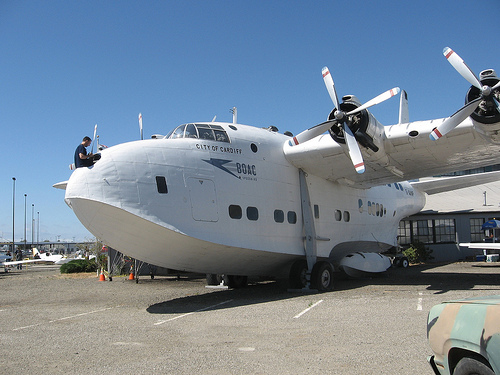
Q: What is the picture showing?
A: It is showing an airport.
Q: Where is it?
A: This is at the airport.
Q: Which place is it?
A: It is an airport.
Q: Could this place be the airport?
A: Yes, it is the airport.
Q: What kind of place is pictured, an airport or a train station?
A: It is an airport.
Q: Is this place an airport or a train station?
A: It is an airport.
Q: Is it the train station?
A: No, it is the airport.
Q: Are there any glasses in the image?
A: No, there are no glasses.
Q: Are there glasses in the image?
A: No, there are no glasses.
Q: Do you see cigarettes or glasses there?
A: No, there are no glasses or cigarettes.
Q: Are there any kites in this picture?
A: No, there are no kites.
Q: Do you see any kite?
A: No, there are no kites.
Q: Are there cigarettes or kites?
A: No, there are no kites or cigarettes.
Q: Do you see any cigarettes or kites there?
A: No, there are no kites or cigarettes.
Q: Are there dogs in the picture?
A: No, there are no dogs.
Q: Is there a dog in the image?
A: No, there are no dogs.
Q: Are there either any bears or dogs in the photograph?
A: No, there are no dogs or bears.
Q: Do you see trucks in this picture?
A: Yes, there is a truck.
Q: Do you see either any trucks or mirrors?
A: Yes, there is a truck.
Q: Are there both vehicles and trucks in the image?
A: Yes, there are both a truck and a vehicle.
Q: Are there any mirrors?
A: No, there are no mirrors.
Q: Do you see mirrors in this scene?
A: No, there are no mirrors.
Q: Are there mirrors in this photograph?
A: No, there are no mirrors.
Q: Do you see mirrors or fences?
A: No, there are no mirrors or fences.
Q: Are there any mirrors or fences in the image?
A: No, there are no mirrors or fences.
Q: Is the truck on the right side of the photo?
A: Yes, the truck is on the right of the image.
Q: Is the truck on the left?
A: No, the truck is on the right of the image.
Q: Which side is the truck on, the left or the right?
A: The truck is on the right of the image.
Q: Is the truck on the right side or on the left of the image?
A: The truck is on the right of the image.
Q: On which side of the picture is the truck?
A: The truck is on the right of the image.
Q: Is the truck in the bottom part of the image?
A: Yes, the truck is in the bottom of the image.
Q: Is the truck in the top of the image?
A: No, the truck is in the bottom of the image.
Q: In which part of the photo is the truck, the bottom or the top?
A: The truck is in the bottom of the image.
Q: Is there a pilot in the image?
A: No, there are no pilots.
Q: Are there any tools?
A: No, there are no tools.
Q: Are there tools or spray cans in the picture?
A: No, there are no tools or spray cans.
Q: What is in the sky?
A: The clouds are in the sky.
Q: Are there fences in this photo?
A: No, there are no fences.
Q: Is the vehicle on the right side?
A: Yes, the vehicle is on the right of the image.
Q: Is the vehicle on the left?
A: No, the vehicle is on the right of the image.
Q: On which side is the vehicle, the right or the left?
A: The vehicle is on the right of the image.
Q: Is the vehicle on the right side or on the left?
A: The vehicle is on the right of the image.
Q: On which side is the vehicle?
A: The vehicle is on the right of the image.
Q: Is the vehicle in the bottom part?
A: Yes, the vehicle is in the bottom of the image.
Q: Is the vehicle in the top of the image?
A: No, the vehicle is in the bottom of the image.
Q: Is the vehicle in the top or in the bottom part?
A: The vehicle is in the bottom of the image.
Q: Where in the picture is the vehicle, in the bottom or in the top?
A: The vehicle is in the bottom of the image.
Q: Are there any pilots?
A: No, there are no pilots.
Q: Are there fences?
A: No, there are no fences.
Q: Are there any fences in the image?
A: No, there are no fences.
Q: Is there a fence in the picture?
A: No, there are no fences.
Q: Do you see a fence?
A: No, there are no fences.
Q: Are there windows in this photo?
A: Yes, there is a window.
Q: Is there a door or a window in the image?
A: Yes, there is a window.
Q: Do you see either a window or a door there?
A: Yes, there is a window.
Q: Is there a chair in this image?
A: No, there are no chairs.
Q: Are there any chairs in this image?
A: No, there are no chairs.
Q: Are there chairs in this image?
A: No, there are no chairs.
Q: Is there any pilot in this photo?
A: No, there are no pilots.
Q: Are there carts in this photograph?
A: No, there are no carts.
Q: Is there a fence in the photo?
A: No, there are no fences.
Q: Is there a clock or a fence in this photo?
A: No, there are no fences or clocks.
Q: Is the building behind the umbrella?
A: Yes, the building is behind the umbrella.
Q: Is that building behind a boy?
A: No, the building is behind the umbrella.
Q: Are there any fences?
A: No, there are no fences.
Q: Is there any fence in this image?
A: No, there are no fences.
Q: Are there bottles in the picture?
A: No, there are no bottles.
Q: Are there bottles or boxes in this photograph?
A: No, there are no bottles or boxes.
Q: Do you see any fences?
A: No, there are no fences.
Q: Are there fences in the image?
A: No, there are no fences.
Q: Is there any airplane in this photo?
A: Yes, there is an airplane.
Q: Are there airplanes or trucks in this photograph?
A: Yes, there is an airplane.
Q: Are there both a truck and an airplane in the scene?
A: Yes, there are both an airplane and a truck.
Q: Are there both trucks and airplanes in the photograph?
A: Yes, there are both an airplane and a truck.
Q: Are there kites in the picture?
A: No, there are no kites.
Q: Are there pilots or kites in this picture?
A: No, there are no kites or pilots.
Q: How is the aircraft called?
A: The aircraft is an airplane.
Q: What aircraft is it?
A: The aircraft is an airplane.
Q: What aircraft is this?
A: This is an airplane.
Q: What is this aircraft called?
A: This is an airplane.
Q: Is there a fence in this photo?
A: No, there are no fences.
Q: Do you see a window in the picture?
A: Yes, there are windows.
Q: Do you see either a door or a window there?
A: Yes, there are windows.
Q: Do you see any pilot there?
A: No, there are no pilots.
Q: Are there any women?
A: No, there are no women.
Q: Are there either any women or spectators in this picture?
A: No, there are no women or spectators.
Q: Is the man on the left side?
A: Yes, the man is on the left of the image.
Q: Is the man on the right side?
A: No, the man is on the left of the image.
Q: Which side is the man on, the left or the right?
A: The man is on the left of the image.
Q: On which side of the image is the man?
A: The man is on the left of the image.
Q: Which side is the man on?
A: The man is on the left of the image.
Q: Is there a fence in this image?
A: No, there are no fences.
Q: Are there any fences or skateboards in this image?
A: No, there are no fences or skateboards.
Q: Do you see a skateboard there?
A: No, there are no skateboards.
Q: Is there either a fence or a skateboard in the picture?
A: No, there are no skateboards or fences.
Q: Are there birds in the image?
A: No, there are no birds.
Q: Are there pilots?
A: No, there are no pilots.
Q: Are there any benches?
A: No, there are no benches.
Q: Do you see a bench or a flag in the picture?
A: No, there are no benches or flags.